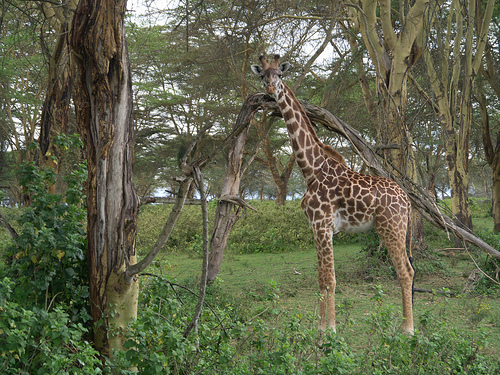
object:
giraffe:
[251, 55, 419, 334]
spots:
[355, 201, 368, 214]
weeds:
[0, 262, 500, 374]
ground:
[0, 241, 500, 375]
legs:
[317, 232, 337, 337]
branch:
[183, 158, 220, 321]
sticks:
[203, 302, 284, 340]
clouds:
[297, 43, 333, 64]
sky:
[113, 10, 455, 108]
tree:
[41, 0, 231, 375]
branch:
[128, 171, 193, 285]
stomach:
[330, 216, 377, 236]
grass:
[0, 197, 497, 375]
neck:
[275, 89, 320, 169]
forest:
[0, 0, 500, 375]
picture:
[0, 1, 497, 375]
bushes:
[110, 186, 303, 251]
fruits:
[53, 245, 67, 266]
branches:
[232, 15, 340, 78]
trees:
[212, 0, 428, 251]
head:
[251, 52, 286, 93]